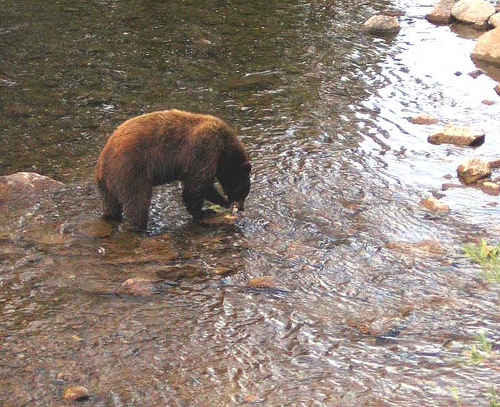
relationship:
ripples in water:
[250, 55, 414, 338] [3, 5, 499, 397]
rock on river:
[359, 8, 403, 39] [3, 5, 499, 397]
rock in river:
[403, 110, 441, 128] [3, 5, 499, 397]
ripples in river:
[250, 55, 414, 338] [3, 5, 499, 397]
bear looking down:
[87, 105, 257, 243] [229, 207, 266, 238]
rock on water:
[421, 126, 488, 154] [3, 5, 499, 397]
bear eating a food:
[87, 105, 257, 243] [229, 207, 247, 220]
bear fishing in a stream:
[87, 105, 257, 243] [3, 5, 499, 397]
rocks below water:
[131, 227, 453, 352] [3, 5, 499, 397]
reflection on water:
[164, 218, 249, 293] [3, 5, 499, 397]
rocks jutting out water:
[357, 4, 499, 223] [3, 5, 499, 397]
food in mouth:
[229, 207, 247, 220] [229, 198, 244, 218]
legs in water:
[98, 203, 218, 229] [3, 5, 499, 397]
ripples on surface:
[250, 55, 414, 338] [3, 5, 499, 397]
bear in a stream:
[87, 105, 257, 243] [3, 5, 499, 397]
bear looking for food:
[87, 105, 257, 243] [229, 207, 266, 238]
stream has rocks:
[3, 5, 499, 397] [357, 4, 499, 223]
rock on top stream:
[466, 28, 499, 67] [3, 5, 499, 397]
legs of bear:
[98, 203, 218, 229] [87, 105, 257, 243]